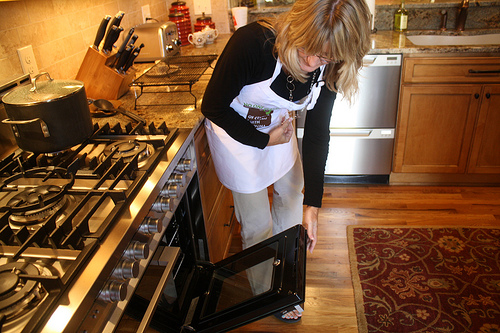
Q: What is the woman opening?
A: The oven door.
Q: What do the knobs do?
A: Control flames and temperature.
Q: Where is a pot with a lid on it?
A: On the back burner.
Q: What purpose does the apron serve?
A: Keep the woman's clothes clean.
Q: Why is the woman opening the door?
A: Check inside the oven.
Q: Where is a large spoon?
A: On the counter top right of the stove.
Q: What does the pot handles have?
A: Silver handles.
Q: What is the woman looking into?
A: The oven.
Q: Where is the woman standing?
A: In the kitchen.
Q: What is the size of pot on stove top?
A: Large.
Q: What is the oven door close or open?
A: It is open.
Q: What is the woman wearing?
A: A white apron.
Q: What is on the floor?
A: A rug.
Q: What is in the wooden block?
A: Knives.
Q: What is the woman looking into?
A: Oven.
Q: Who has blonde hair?
A: The woman.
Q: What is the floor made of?
A: Wood.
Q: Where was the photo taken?
A: Kitchen.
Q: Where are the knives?
A: Knife block.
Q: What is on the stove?
A: Pot.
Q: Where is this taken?
A: In a kitchen.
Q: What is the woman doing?
A: Cooking.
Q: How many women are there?
A: One.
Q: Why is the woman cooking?
A: To feed people.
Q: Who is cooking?
A: The woman.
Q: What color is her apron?
A: White.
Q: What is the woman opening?
A: The oven.